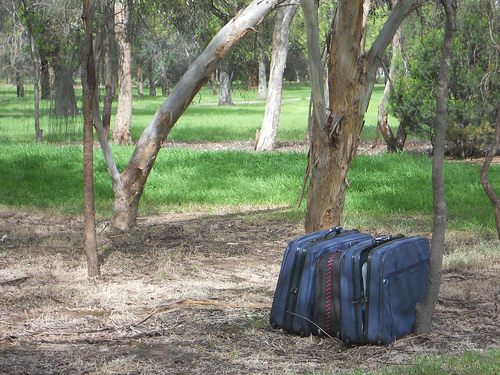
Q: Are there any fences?
A: No, there are no fences.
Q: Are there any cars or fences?
A: No, there are no fences or cars.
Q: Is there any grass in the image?
A: Yes, there is grass.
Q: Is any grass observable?
A: Yes, there is grass.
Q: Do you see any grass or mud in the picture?
A: Yes, there is grass.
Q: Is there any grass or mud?
A: Yes, there is grass.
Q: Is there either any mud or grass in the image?
A: Yes, there is grass.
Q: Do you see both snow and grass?
A: No, there is grass but no snow.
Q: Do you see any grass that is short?
A: Yes, there is short grass.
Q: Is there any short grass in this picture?
A: Yes, there is short grass.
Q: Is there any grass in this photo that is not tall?
A: Yes, there is short grass.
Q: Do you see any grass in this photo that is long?
A: Yes, there is long grass.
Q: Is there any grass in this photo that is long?
A: Yes, there is grass that is long.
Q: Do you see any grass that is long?
A: Yes, there is grass that is long.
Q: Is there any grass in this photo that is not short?
A: Yes, there is long grass.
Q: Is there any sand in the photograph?
A: No, there is no sand.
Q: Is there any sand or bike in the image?
A: No, there are no sand or bikes.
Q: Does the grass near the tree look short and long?
A: Yes, the grass is short and long.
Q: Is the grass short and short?
A: No, the grass is short but long.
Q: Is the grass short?
A: Yes, the grass is short.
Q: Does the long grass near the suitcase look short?
A: Yes, the grass is short.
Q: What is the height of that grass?
A: The grass is short.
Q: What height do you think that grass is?
A: The grass is short.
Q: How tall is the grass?
A: The grass is short.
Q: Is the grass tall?
A: No, the grass is short.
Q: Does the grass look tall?
A: No, the grass is short.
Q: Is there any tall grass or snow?
A: No, there is grass but it is short.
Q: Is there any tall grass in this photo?
A: No, there is grass but it is short.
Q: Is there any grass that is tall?
A: No, there is grass but it is short.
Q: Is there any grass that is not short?
A: No, there is grass but it is short.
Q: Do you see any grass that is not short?
A: No, there is grass but it is short.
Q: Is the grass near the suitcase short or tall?
A: The grass is short.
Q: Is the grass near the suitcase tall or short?
A: The grass is short.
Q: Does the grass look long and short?
A: Yes, the grass is long and short.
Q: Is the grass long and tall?
A: No, the grass is long but short.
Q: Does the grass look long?
A: Yes, the grass is long.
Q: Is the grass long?
A: Yes, the grass is long.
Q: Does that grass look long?
A: Yes, the grass is long.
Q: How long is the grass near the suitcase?
A: The grass is long.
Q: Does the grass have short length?
A: No, the grass is long.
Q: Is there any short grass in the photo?
A: No, there is grass but it is long.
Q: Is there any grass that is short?
A: No, there is grass but it is long.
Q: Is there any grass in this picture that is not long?
A: No, there is grass but it is long.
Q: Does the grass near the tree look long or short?
A: The grass is long.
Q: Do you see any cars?
A: No, there are no cars.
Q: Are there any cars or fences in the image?
A: No, there are no cars or fences.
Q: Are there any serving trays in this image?
A: No, there are no serving trays.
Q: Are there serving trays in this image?
A: No, there are no serving trays.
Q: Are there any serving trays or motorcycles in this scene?
A: No, there are no serving trays or motorcycles.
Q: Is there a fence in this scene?
A: No, there are no fences.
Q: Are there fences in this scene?
A: No, there are no fences.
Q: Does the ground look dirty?
A: Yes, the ground is dirty.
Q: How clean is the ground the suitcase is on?
A: The ground is dirty.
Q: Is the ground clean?
A: No, the ground is dirty.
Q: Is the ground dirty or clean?
A: The ground is dirty.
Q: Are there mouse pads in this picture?
A: No, there are no mouse pads.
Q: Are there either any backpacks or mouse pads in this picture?
A: No, there are no mouse pads or backpacks.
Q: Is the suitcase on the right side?
A: Yes, the suitcase is on the right of the image.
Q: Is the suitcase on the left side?
A: No, the suitcase is on the right of the image.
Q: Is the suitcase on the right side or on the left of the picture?
A: The suitcase is on the right of the image.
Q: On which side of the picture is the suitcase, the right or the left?
A: The suitcase is on the right of the image.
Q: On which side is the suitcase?
A: The suitcase is on the right of the image.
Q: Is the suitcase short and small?
A: Yes, the suitcase is short and small.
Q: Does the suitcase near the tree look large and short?
A: No, the suitcase is short but small.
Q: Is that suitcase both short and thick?
A: Yes, the suitcase is short and thick.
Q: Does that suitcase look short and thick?
A: Yes, the suitcase is short and thick.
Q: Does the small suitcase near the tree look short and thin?
A: No, the suitcase is short but thick.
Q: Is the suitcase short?
A: Yes, the suitcase is short.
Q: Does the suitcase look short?
A: Yes, the suitcase is short.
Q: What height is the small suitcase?
A: The suitcase is short.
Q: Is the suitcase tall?
A: No, the suitcase is short.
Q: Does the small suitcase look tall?
A: No, the suitcase is short.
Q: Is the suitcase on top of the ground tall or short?
A: The suitcase is short.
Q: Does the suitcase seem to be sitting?
A: Yes, the suitcase is sitting.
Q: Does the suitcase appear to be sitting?
A: Yes, the suitcase is sitting.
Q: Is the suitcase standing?
A: No, the suitcase is sitting.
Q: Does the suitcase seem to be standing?
A: No, the suitcase is sitting.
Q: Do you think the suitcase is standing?
A: No, the suitcase is sitting.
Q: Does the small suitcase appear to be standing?
A: No, the suitcase is sitting.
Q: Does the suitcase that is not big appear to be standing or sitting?
A: The suitcase is sitting.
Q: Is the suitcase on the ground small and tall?
A: No, the suitcase is small but short.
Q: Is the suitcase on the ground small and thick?
A: Yes, the suitcase is small and thick.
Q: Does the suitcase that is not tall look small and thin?
A: No, the suitcase is small but thick.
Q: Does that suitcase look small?
A: Yes, the suitcase is small.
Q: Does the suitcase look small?
A: Yes, the suitcase is small.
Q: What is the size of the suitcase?
A: The suitcase is small.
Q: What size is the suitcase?
A: The suitcase is small.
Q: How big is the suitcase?
A: The suitcase is small.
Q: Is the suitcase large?
A: No, the suitcase is small.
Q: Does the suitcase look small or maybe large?
A: The suitcase is small.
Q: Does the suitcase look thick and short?
A: Yes, the suitcase is thick and short.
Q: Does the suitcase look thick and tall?
A: No, the suitcase is thick but short.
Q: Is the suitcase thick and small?
A: Yes, the suitcase is thick and small.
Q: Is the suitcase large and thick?
A: No, the suitcase is thick but small.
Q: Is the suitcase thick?
A: Yes, the suitcase is thick.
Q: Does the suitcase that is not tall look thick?
A: Yes, the suitcase is thick.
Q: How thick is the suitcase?
A: The suitcase is thick.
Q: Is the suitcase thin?
A: No, the suitcase is thick.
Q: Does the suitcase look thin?
A: No, the suitcase is thick.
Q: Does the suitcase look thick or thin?
A: The suitcase is thick.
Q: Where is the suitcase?
A: The suitcase is on the ground.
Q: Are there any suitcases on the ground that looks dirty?
A: Yes, there is a suitcase on the ground.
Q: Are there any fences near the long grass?
A: No, there is a suitcase near the grass.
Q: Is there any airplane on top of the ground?
A: No, there is a suitcase on top of the ground.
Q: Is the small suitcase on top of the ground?
A: Yes, the suitcase is on top of the ground.